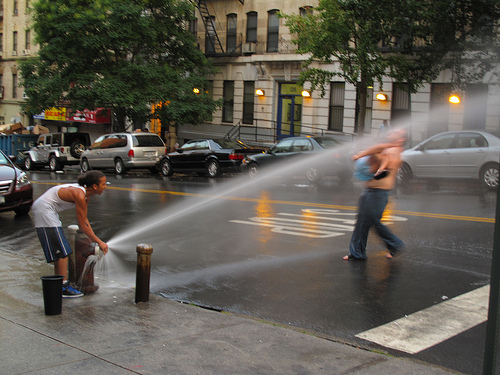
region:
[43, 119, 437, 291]
People playing in the water.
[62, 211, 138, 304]
Water coming from the fire hydrant.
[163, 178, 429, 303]
The street is wet.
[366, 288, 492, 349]
A thick white line in the road.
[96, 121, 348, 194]
Cars parked by the sidewalk.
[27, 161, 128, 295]
A man turning on the fire hydrant.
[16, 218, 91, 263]
The man is wearing blue shorts.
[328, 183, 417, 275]
The person is wearing blue pants.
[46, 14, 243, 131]
A tree in front of the building.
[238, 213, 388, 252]
The word "stop" in the middle of the road.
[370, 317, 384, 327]
edge of a line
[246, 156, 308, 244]
part of a plash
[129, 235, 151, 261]
edge of a tank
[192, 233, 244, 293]
part of a water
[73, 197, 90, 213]
part of a shoulder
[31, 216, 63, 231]
edge of a veast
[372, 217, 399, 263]
part of a jeans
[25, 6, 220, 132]
A large tree.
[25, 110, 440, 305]
The people are playing with the fire hydrant.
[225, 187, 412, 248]
"STOP" is written on the street.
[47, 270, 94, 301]
The man is wearing sneakers.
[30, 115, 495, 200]
Cars parked on the side of the street.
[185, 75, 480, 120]
The building's exterior lights are on.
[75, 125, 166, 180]
A silver minivan.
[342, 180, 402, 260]
The man is wearing jeans.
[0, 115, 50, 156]
A dumpster full of boxes.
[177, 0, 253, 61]
A fire escape.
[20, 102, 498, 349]
two people breaking a hydrant and using it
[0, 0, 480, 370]
scene during the day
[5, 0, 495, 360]
a scene downtown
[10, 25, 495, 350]
a scene outside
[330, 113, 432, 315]
a man shirtless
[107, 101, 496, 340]
white sprayed water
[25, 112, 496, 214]
row of parked cars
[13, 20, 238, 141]
a green tree here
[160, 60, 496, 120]
a row of lights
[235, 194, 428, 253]
word STOP on road here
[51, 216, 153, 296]
fire hydrant is open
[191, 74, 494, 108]
lights are on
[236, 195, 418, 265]
STOP is written on the road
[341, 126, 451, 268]
man and kid are getting wet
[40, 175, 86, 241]
man is wearing a tank top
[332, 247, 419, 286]
man has no shoes on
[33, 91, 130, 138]
awning over door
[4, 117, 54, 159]
dumpster is full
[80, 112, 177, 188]
silver minivan parked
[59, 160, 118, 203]
man has a ponytail